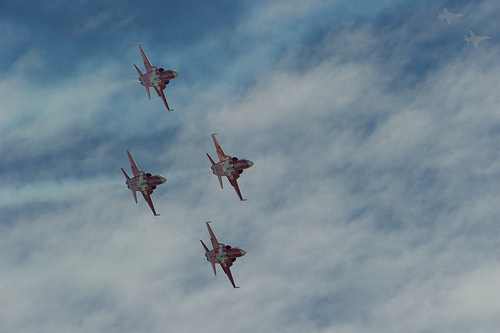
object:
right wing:
[140, 190, 161, 216]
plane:
[120, 148, 167, 216]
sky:
[0, 0, 499, 332]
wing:
[125, 147, 140, 175]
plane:
[133, 43, 180, 112]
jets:
[436, 3, 492, 48]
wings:
[210, 132, 247, 202]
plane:
[205, 133, 254, 202]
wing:
[219, 264, 240, 289]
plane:
[199, 220, 247, 288]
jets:
[120, 43, 253, 289]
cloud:
[0, 0, 499, 333]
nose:
[239, 159, 254, 169]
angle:
[118, 43, 255, 289]